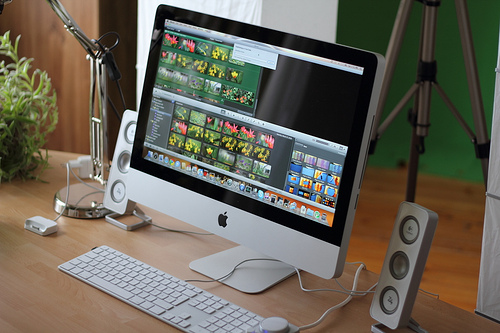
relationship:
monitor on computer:
[121, 2, 395, 291] [119, 5, 399, 303]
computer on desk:
[119, 5, 399, 303] [2, 143, 497, 332]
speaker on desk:
[367, 198, 444, 332] [2, 143, 497, 332]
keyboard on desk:
[55, 240, 306, 330] [2, 143, 497, 332]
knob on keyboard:
[252, 312, 299, 331] [55, 240, 306, 330]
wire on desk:
[182, 253, 376, 302] [2, 143, 497, 332]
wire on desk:
[54, 158, 75, 225] [2, 143, 497, 332]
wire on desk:
[130, 206, 213, 250] [2, 143, 497, 332]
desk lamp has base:
[42, 0, 129, 226] [49, 173, 111, 224]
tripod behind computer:
[364, 0, 492, 215] [119, 5, 399, 303]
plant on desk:
[0, 25, 64, 195] [2, 143, 497, 332]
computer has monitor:
[119, 5, 399, 303] [121, 2, 395, 291]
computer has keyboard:
[119, 5, 399, 303] [55, 240, 306, 330]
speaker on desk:
[101, 102, 156, 237] [2, 143, 497, 332]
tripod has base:
[364, 0, 492, 215] [405, 139, 424, 201]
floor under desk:
[344, 163, 488, 327] [2, 143, 497, 332]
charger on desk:
[15, 211, 62, 239] [2, 143, 497, 332]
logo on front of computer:
[211, 206, 237, 234] [119, 5, 399, 303]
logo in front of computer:
[211, 206, 237, 234] [119, 5, 399, 303]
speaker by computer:
[367, 198, 444, 332] [119, 5, 399, 303]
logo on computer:
[211, 206, 237, 234] [119, 5, 399, 303]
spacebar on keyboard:
[86, 271, 137, 304] [55, 240, 306, 330]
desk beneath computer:
[2, 143, 497, 332] [119, 5, 399, 303]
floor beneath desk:
[344, 163, 488, 327] [2, 143, 497, 332]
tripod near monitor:
[364, 0, 492, 215] [121, 2, 395, 291]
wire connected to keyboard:
[182, 253, 376, 302] [55, 240, 306, 330]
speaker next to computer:
[367, 198, 444, 332] [119, 5, 399, 303]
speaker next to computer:
[101, 102, 156, 237] [119, 5, 399, 303]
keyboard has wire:
[55, 240, 306, 330] [182, 253, 376, 302]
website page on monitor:
[135, 25, 351, 236] [121, 2, 395, 291]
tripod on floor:
[364, 0, 492, 215] [344, 163, 488, 327]